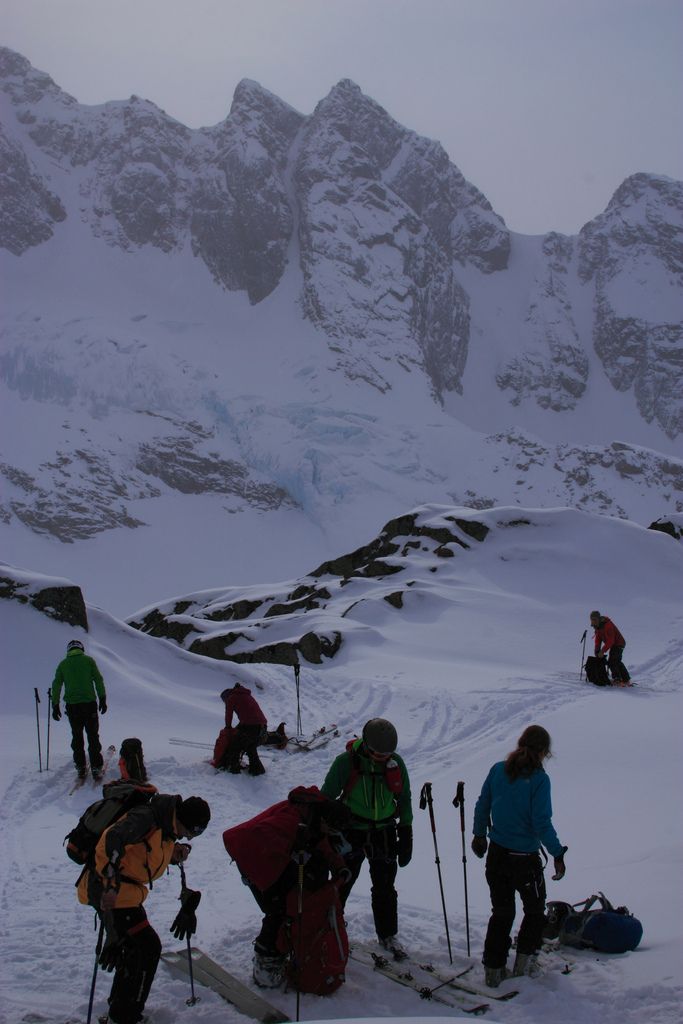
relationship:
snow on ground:
[408, 568, 569, 716] [3, 428, 659, 1020]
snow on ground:
[70, 284, 308, 471] [3, 428, 659, 1020]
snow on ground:
[2, 563, 680, 1018] [4, 495, 675, 1021]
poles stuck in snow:
[409, 760, 508, 972] [1, 470, 677, 1020]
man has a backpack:
[42, 772, 228, 876] [63, 776, 162, 872]